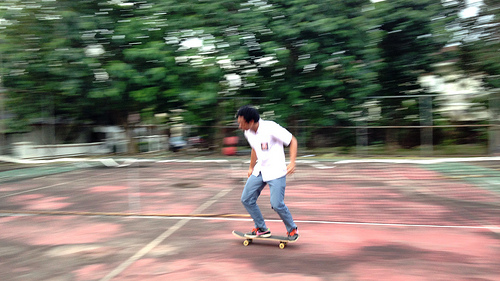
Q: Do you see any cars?
A: No, there are no cars.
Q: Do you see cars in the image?
A: No, there are no cars.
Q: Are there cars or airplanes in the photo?
A: No, there are no cars or airplanes.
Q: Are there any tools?
A: No, there are no tools.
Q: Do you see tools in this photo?
A: No, there are no tools.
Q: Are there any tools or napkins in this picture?
A: No, there are no tools or napkins.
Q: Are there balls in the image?
A: No, there are no balls.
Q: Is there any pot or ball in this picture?
A: No, there are no balls or pots.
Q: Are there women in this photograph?
A: No, there are no women.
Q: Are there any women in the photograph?
A: No, there are no women.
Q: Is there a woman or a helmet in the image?
A: No, there are no women or helmets.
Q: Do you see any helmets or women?
A: No, there are no women or helmets.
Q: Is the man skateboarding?
A: Yes, the man is skateboarding.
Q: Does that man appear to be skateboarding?
A: Yes, the man is skateboarding.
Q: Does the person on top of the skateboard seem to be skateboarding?
A: Yes, the man is skateboarding.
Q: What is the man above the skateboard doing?
A: The man is skateboarding.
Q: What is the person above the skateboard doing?
A: The man is skateboarding.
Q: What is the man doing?
A: The man is skateboarding.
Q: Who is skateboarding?
A: The man is skateboarding.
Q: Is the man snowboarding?
A: No, the man is skateboarding.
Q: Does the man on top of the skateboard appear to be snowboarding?
A: No, the man is skateboarding.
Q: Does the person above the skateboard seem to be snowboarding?
A: No, the man is skateboarding.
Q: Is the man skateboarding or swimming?
A: The man is skateboarding.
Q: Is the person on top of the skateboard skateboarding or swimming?
A: The man is skateboarding.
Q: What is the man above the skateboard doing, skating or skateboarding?
A: The man is skateboarding.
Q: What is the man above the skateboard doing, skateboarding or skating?
A: The man is skateboarding.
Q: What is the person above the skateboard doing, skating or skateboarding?
A: The man is skateboarding.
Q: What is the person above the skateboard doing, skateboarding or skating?
A: The man is skateboarding.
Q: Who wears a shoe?
A: The man wears a shoe.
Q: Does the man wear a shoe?
A: Yes, the man wears a shoe.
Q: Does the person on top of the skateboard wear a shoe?
A: Yes, the man wears a shoe.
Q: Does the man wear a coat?
A: No, the man wears a shoe.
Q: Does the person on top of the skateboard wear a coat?
A: No, the man wears a shoe.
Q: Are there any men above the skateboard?
A: Yes, there is a man above the skateboard.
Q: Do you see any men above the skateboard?
A: Yes, there is a man above the skateboard.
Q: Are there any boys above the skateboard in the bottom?
A: No, there is a man above the skateboard.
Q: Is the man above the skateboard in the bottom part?
A: Yes, the man is above the skateboard.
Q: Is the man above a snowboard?
A: No, the man is above the skateboard.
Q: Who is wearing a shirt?
A: The man is wearing a shirt.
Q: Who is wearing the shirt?
A: The man is wearing a shirt.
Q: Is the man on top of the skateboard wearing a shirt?
A: Yes, the man is wearing a shirt.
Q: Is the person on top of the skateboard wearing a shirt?
A: Yes, the man is wearing a shirt.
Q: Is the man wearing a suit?
A: No, the man is wearing a shirt.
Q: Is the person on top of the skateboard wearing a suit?
A: No, the man is wearing a shirt.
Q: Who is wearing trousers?
A: The man is wearing trousers.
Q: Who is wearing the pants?
A: The man is wearing trousers.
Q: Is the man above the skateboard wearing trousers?
A: Yes, the man is wearing trousers.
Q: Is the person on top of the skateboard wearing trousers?
A: Yes, the man is wearing trousers.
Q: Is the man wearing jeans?
A: No, the man is wearing trousers.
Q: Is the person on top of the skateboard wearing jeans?
A: No, the man is wearing trousers.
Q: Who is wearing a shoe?
A: The man is wearing a shoe.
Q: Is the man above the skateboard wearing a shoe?
A: Yes, the man is wearing a shoe.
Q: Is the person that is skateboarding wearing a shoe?
A: Yes, the man is wearing a shoe.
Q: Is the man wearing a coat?
A: No, the man is wearing a shoe.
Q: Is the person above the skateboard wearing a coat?
A: No, the man is wearing a shoe.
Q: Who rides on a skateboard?
A: The man rides on a skateboard.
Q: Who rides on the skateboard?
A: The man rides on a skateboard.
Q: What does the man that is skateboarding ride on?
A: The man rides on a skateboard.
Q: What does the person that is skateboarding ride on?
A: The man rides on a skateboard.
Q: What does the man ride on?
A: The man rides on a skateboard.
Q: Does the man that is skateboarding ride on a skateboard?
A: Yes, the man rides on a skateboard.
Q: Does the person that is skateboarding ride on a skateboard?
A: Yes, the man rides on a skateboard.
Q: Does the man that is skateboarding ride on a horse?
A: No, the man rides on a skateboard.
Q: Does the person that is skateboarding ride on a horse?
A: No, the man rides on a skateboard.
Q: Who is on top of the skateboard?
A: The man is on top of the skateboard.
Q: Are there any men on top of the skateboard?
A: Yes, there is a man on top of the skateboard.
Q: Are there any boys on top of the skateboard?
A: No, there is a man on top of the skateboard.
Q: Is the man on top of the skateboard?
A: Yes, the man is on top of the skateboard.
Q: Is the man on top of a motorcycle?
A: No, the man is on top of the skateboard.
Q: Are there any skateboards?
A: Yes, there is a skateboard.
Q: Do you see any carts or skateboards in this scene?
A: Yes, there is a skateboard.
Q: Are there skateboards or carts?
A: Yes, there is a skateboard.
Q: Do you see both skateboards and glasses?
A: No, there is a skateboard but no glasses.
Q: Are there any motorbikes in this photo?
A: No, there are no motorbikes.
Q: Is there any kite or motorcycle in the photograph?
A: No, there are no motorcycles or kites.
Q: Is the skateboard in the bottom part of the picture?
A: Yes, the skateboard is in the bottom of the image.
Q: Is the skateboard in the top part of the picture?
A: No, the skateboard is in the bottom of the image.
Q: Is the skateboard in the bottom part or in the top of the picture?
A: The skateboard is in the bottom of the image.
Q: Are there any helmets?
A: No, there are no helmets.